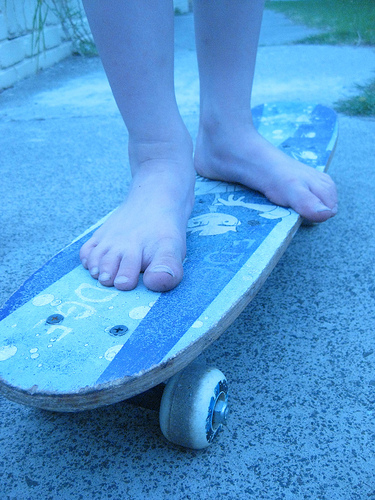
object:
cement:
[1, 26, 34, 46]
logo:
[184, 205, 243, 238]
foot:
[78, 148, 198, 293]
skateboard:
[1, 92, 343, 452]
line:
[135, 154, 179, 166]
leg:
[81, 0, 196, 156]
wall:
[1, 0, 96, 90]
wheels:
[160, 359, 231, 451]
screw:
[46, 313, 63, 326]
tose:
[261, 133, 340, 220]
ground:
[0, 3, 373, 500]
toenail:
[312, 201, 332, 213]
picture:
[0, 8, 371, 499]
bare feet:
[193, 128, 341, 222]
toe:
[289, 181, 332, 222]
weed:
[63, 13, 97, 65]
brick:
[15, 54, 39, 81]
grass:
[264, 1, 374, 119]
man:
[78, 0, 342, 296]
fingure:
[141, 236, 185, 293]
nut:
[215, 399, 231, 424]